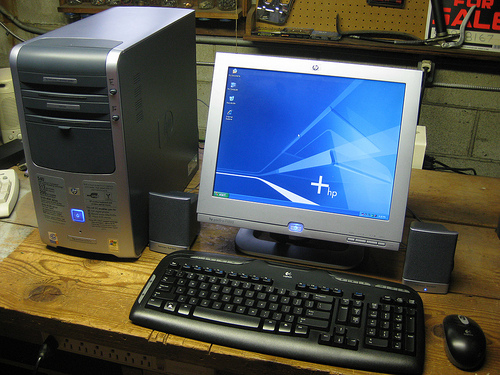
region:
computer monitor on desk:
[193, 43, 431, 236]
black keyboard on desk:
[138, 250, 428, 367]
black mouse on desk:
[436, 297, 478, 353]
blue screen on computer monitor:
[213, 76, 384, 219]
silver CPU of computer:
[16, 20, 186, 260]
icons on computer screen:
[221, 71, 243, 121]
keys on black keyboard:
[168, 269, 426, 351]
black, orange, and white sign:
[429, 3, 487, 80]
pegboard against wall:
[249, 7, 431, 45]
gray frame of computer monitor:
[198, 46, 418, 251]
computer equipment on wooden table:
[7, 6, 492, 371]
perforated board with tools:
[242, 0, 428, 50]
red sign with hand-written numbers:
[420, 0, 495, 56]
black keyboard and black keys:
[125, 245, 425, 370]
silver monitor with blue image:
[195, 45, 420, 251]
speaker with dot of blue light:
[397, 210, 457, 290]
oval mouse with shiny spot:
[437, 306, 487, 366]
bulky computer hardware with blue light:
[7, 1, 197, 256]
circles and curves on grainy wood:
[2, 236, 142, 323]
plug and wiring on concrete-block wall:
[412, 57, 495, 173]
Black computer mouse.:
[444, 313, 486, 372]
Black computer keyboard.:
[136, 250, 421, 373]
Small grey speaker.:
[407, 220, 454, 296]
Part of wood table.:
[33, 260, 105, 305]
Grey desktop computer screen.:
[199, 49, 415, 251]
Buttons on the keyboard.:
[191, 283, 256, 308]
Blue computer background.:
[262, 104, 327, 134]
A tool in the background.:
[315, 18, 422, 48]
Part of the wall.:
[446, 104, 491, 154]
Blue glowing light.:
[70, 209, 85, 221]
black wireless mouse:
[440, 305, 494, 373]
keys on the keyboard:
[211, 265, 274, 309]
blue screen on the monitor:
[230, 75, 373, 210]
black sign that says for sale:
[430, 3, 493, 32]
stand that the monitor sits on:
[230, 230, 370, 270]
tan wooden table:
[46, 277, 96, 312]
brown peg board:
[297, 5, 389, 20]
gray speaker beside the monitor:
[403, 218, 461, 300]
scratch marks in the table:
[142, 325, 169, 343]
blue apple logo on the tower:
[70, 203, 84, 224]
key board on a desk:
[130, 245, 425, 373]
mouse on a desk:
[430, 300, 490, 371]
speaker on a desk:
[400, 212, 460, 292]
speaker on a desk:
[145, 175, 196, 251]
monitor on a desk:
[197, 40, 423, 235]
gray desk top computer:
[10, 31, 140, 256]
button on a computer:
[102, 81, 127, 136]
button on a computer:
[45, 120, 80, 135]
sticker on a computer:
[93, 230, 123, 260]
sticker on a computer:
[42, 220, 66, 254]